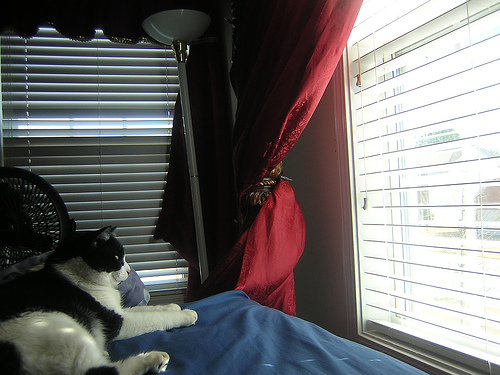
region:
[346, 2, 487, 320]
white blinds on window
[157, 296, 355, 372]
blue sheet on bed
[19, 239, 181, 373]
cat lying on bed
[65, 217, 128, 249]
cat has black ears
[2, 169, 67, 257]
wooden chair behind cat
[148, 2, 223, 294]
light pole near window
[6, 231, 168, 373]
a cat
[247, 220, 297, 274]
a red curtain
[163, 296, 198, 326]
the cats front paws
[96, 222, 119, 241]
the cats ears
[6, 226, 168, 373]
the cat is black and white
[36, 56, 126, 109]
the blinds are closed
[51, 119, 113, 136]
blinds are open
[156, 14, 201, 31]
a lamp shade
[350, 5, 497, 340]
a window in the room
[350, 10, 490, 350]
blinds over the window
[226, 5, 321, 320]
a bed post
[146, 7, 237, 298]
a white lamp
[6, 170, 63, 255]
a fan behind the cat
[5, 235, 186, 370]
a cat laying on a bed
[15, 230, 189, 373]
a black and white cat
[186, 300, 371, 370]
the blue bed sheet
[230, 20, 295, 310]
a red curtain wrapped around the bed post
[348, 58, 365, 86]
the string on the blinds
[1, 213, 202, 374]
cat on the bed.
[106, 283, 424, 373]
blue sheets on the bed.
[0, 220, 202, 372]
black and white colored cat.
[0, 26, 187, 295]
blinds on the window.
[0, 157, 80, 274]
Fan in the background.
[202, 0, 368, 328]
Red drapes on the window.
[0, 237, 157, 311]
Pillow on the bed.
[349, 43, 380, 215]
Cord on the blinds.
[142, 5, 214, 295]
floor lamp in the room.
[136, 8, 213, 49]
glass lamp shade on the lamp.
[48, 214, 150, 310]
the head of a cat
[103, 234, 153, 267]
the eye of a cat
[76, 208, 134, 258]
the ear of a cat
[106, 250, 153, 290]
the nose of a cat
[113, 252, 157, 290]
the mouth of a cat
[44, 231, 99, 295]
the neck of a cat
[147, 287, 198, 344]
the paw of a cat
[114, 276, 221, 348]
the legs of a cat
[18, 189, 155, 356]
the body of a cat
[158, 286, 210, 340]
the claws of a cat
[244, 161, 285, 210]
a wrap around a curtain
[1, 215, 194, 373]
a black and white cat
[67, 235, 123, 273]
black and white face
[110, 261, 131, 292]
mouth of a cat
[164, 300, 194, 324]
paws of a cat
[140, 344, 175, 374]
back paws of a cat